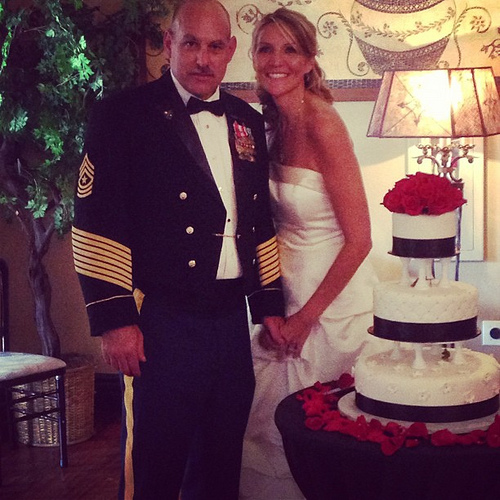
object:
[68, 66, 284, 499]
uniform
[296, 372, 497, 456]
petals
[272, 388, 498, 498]
table cloth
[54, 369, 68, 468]
legs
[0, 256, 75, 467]
chair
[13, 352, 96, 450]
basket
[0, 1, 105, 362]
tree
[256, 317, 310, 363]
hands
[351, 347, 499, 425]
tier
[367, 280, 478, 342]
tier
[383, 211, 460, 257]
tier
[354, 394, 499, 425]
trimming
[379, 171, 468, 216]
roses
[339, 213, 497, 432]
wedding cake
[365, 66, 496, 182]
lamp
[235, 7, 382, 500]
bride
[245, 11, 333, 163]
hair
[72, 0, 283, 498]
groom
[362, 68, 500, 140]
lamp shade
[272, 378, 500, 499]
table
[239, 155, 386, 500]
wedding dress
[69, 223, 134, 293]
stripes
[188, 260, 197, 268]
buttons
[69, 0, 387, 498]
couple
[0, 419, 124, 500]
flooring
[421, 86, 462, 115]
light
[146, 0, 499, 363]
wall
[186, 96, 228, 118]
bow tie